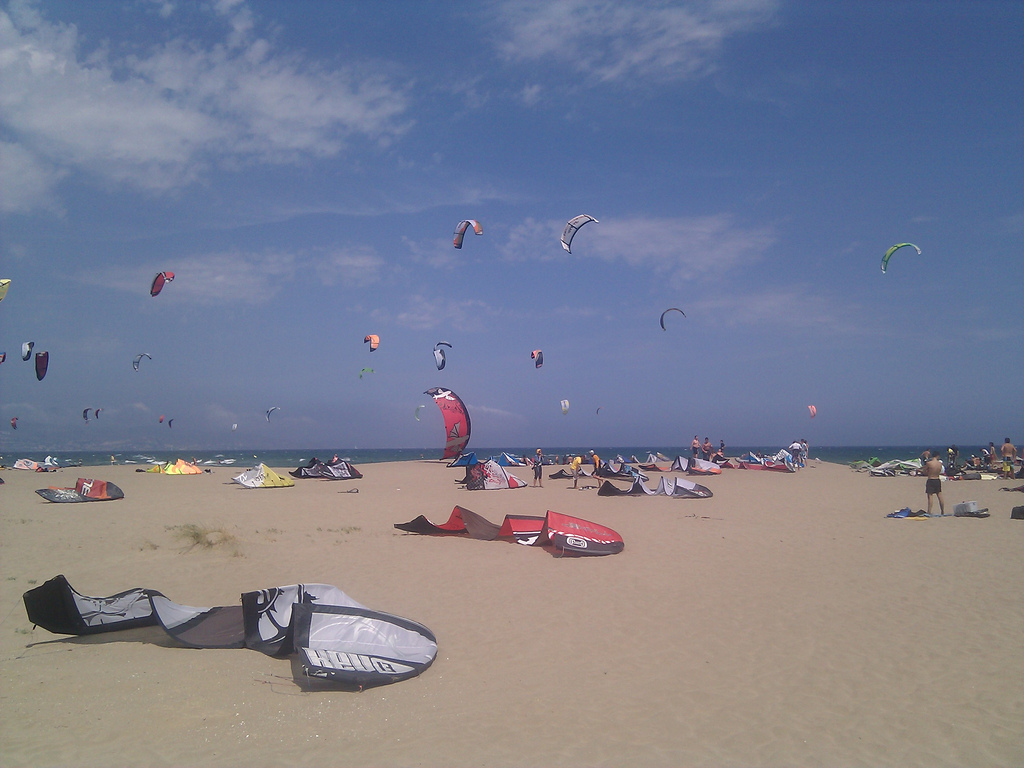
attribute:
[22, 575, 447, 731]
kite — grey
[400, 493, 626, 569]
kite — black, red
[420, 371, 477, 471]
kite — red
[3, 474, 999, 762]
ground — black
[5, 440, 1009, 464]
ocean — in the distance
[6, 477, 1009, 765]
sand — black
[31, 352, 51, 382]
kite — colorful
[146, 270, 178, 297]
kite — colorful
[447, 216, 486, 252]
kite — colorful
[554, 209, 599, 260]
kite — colorful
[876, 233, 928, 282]
kite — colorful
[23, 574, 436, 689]
kite — black, white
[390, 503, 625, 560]
kite — white, red, black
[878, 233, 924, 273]
kite — green